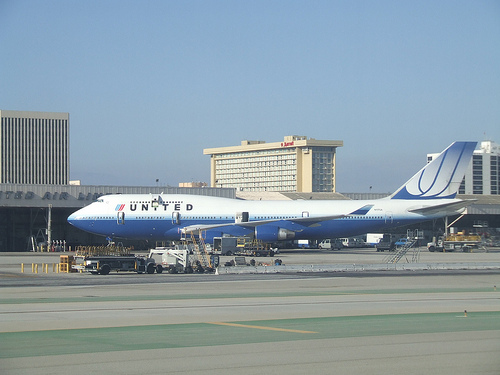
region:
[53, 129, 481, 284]
airplane parked at airport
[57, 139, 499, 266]
airplane is blue and white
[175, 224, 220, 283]
rolling stairs parked by airplane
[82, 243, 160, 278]
small trailer parked by plane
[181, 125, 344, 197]
large building behind airport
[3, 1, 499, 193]
sky is clear and blue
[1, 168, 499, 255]
airport behind the airplane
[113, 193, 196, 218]
airplane belongs to united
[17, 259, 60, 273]
yellow poles marking parking spot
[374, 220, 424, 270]
stair ramp parked at rear of plane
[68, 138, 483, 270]
Blue and white airplane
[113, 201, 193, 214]
Name of the airline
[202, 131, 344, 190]
Large building in the background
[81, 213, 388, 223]
Row of windows on the left side of the airplane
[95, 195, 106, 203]
Front window of the airplane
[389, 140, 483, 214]
Tail of the airplane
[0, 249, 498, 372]
Road way for the airplane to land on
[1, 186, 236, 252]
Building near the plane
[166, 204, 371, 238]
Left wing of the airplane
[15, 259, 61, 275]
Several yellow cones or barriers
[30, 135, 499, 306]
An airplane sitting on the tarmac.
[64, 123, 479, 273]
A blue and white airplane.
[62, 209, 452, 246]
Bottom half of the airplane is blue.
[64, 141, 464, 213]
The top part of the airplane is mostly white.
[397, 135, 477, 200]
The tail section of an airplane.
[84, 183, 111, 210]
The cockpit windows of an airplane.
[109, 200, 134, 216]
The logo for the airline.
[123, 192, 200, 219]
The name of the airline UNITED.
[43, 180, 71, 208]
The word AIR on the front of a building.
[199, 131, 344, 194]
A white building in the background.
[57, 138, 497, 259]
united airplane by the airport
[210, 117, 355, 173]
marriot hotel by the airport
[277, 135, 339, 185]
marriot hotel by the airport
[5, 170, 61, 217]
united airline terminal in the airport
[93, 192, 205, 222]
united logo on the airplane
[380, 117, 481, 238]
airplane tail on the runway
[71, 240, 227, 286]
luggage carried by the airport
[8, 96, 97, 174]
another hotel by the airport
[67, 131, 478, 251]
blue and white airplane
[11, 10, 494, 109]
clear blue cloudless sky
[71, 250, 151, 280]
small cart on concrete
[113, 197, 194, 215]
black text on white airplane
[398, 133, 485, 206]
tail of an airplane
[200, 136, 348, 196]
tan building behind airplane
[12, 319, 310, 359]
green paint on the ground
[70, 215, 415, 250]
blue paint on white airplane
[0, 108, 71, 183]
building with vertical windows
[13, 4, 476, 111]
bright blue sky